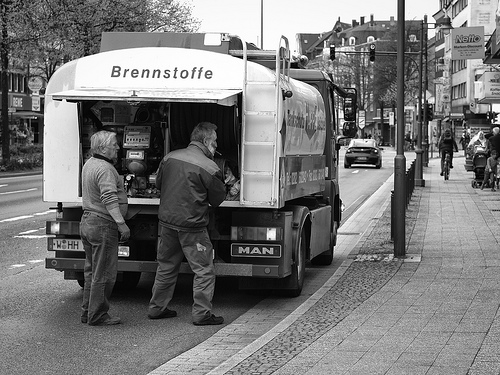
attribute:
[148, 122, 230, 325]
man — standing, outdoors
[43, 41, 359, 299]
truck — rear facing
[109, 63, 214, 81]
logo — word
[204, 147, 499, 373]
sidewalk — brick, layered brick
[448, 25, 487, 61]
sign — hanging, white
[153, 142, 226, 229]
jacket — two tone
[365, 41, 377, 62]
traffic ligh — lit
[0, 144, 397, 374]
road — tar covered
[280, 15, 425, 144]
buildings — distant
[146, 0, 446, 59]
sky — daytime